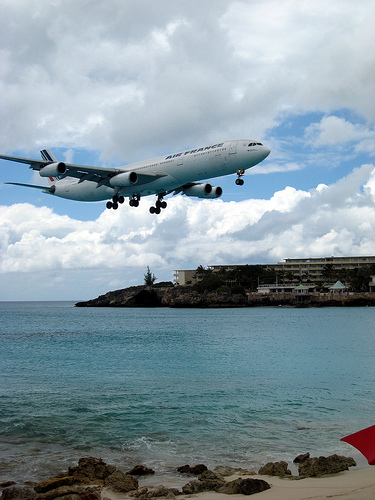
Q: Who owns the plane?
A: Air France.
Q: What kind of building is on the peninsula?
A: Hotel.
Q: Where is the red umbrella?
A: On the beach on the bottom right.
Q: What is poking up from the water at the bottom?
A: Rocks.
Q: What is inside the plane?
A: Passengers.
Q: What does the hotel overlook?
A: The water.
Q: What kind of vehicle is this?
A: Airplane.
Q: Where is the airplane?
A: Sky.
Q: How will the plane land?
A: On wheels.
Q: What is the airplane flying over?
A: Body of water.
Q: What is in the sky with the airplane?
A: Clouds.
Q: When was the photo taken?
A: Daytime.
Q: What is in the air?
A: Plane.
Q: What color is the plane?
A: White.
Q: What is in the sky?
A: Clouds.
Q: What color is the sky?
A: Blue.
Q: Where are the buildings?
A: Other side of water.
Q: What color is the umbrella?
A: Red.